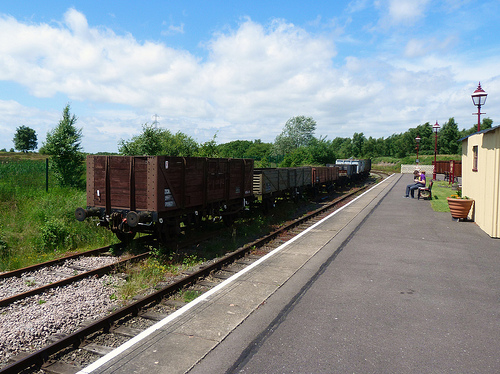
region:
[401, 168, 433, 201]
Person is sitting on bench.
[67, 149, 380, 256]
Train is parked.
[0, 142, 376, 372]
Train is parked on train tracks.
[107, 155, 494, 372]
The pavement is grey.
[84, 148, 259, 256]
The cargo car of the train is brown.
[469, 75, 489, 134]
The night lamp is off.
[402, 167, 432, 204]
Two people are sitting on a bench.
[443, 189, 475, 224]
The flower pot has orange flowers in it.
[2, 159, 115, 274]
The foliage is overgrown.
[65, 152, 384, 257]
Train is parked outside.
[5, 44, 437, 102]
a lot of white clouds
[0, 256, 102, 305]
part of the railroad tracks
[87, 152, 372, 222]
the train with several carriages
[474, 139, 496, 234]
a yellow wall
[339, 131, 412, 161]
green trees in the distance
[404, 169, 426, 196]
a person with a kid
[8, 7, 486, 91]
a beautiful sunny day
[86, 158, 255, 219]
the last wagon of the train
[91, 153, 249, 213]
a brwon wagon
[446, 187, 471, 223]
a seedling planted in a brown jar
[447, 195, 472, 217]
large terra cotta planter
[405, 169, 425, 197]
person in purple shirt sitting on the bench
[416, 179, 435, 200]
red bench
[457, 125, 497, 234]
one side of a yellow building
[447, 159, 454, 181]
red wooden sign in the grass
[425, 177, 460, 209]
small section of green grass behind bench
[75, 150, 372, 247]
train on the tracks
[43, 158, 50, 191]
black fence post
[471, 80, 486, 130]
tall red street light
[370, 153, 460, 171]
green and dirt hill in the background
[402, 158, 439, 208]
People sitting on bench.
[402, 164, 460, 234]
Bench on pavement near grass.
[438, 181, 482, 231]
Large brown pot near building.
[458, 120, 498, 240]
White building behind people.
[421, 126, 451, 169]
Tall red pole with light on top.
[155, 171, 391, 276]
Edge of concrete is painted white.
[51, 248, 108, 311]
Gravel underneath and next to tracks.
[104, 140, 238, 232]
Brown colored train car on tracks.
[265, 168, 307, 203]
Gray colored train car on tracks.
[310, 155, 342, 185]
Orangish brown colored train car.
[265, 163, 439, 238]
a bench on a platform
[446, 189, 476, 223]
a big red pot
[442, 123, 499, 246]
a yellow building behind a pot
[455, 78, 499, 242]
a street light behind a building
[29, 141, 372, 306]
a train on the rails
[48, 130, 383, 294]
a freight train on rails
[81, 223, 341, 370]
border of platform is color white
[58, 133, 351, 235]
cars of train are brown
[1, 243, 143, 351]
there are gravel on rails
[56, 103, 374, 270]
green trees behind a freight train